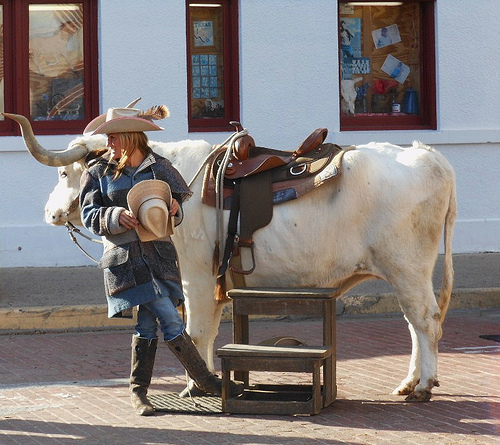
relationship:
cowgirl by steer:
[76, 106, 246, 416] [5, 97, 457, 404]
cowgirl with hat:
[76, 106, 246, 416] [79, 106, 162, 139]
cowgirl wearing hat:
[76, 106, 246, 416] [79, 106, 162, 139]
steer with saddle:
[5, 97, 457, 404] [216, 118, 343, 276]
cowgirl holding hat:
[76, 106, 246, 416] [79, 106, 162, 139]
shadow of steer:
[298, 393, 498, 437] [5, 97, 457, 404]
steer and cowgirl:
[5, 97, 457, 404] [76, 106, 246, 416]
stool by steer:
[218, 284, 343, 416] [5, 97, 457, 404]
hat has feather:
[79, 106, 162, 139] [135, 104, 168, 121]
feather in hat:
[135, 104, 168, 121] [79, 106, 162, 139]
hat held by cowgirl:
[79, 106, 162, 139] [76, 106, 246, 416]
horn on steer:
[1, 110, 89, 167] [5, 97, 457, 404]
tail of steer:
[436, 177, 459, 337] [5, 97, 457, 404]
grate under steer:
[151, 380, 234, 416] [5, 97, 457, 404]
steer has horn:
[5, 97, 457, 404] [1, 110, 89, 167]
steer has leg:
[5, 97, 457, 404] [375, 253, 438, 406]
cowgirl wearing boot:
[76, 106, 246, 416] [168, 325, 247, 399]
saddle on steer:
[216, 118, 343, 276] [5, 97, 457, 404]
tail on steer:
[436, 177, 459, 337] [5, 97, 457, 404]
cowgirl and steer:
[76, 106, 246, 416] [5, 97, 457, 404]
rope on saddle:
[180, 123, 251, 247] [216, 118, 343, 276]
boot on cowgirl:
[168, 325, 247, 399] [76, 106, 246, 416]